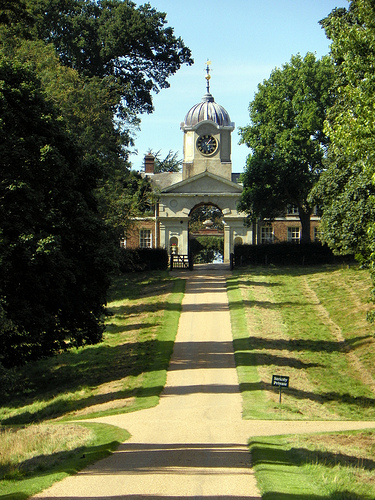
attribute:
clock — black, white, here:
[196, 133, 219, 156]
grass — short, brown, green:
[0, 263, 373, 499]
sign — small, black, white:
[269, 374, 290, 388]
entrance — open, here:
[188, 205, 226, 267]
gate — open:
[172, 253, 191, 269]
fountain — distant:
[201, 217, 216, 231]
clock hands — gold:
[205, 136, 216, 148]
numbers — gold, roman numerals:
[198, 136, 216, 153]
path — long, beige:
[34, 264, 262, 498]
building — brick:
[117, 55, 324, 268]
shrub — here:
[132, 247, 169, 272]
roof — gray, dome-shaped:
[179, 96, 234, 134]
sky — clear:
[47, 1, 355, 172]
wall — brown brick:
[113, 220, 329, 249]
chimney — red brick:
[143, 153, 157, 174]